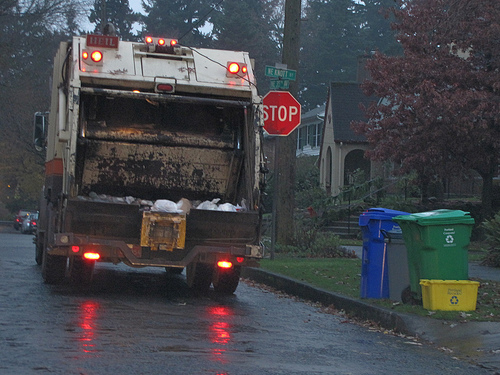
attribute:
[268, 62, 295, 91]
street signs — green, white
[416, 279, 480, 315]
recycling bin — yellow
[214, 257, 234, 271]
rear light — red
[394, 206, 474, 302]
trash can — green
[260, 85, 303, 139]
sign — red, white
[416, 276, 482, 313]
bin — yellow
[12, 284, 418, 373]
ground — wet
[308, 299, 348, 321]
leaves — brown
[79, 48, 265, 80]
lights — red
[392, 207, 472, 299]
garbage bin — large, green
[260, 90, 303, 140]
sign — red, white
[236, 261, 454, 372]
grey curb — gray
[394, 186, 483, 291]
bin — green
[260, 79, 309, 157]
stop sign — red, white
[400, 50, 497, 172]
leaves — red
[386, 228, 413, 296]
trash can — gray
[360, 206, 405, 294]
bin — blue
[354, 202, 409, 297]
trash can — blue trash 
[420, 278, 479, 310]
recycling bin — yellow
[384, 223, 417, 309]
trash can — gray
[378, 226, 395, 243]
handle — black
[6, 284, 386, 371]
road — wet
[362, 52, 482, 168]
leaves — dead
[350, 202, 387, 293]
trash — blue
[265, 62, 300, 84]
sign — white street , green 